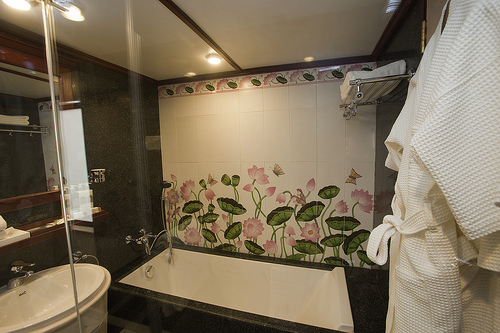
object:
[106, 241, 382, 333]
bathtub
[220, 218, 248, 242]
leaves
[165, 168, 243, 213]
flowers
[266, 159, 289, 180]
butterfly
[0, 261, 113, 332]
sink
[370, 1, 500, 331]
robe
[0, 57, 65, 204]
mirror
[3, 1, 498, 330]
bathroom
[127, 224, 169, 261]
spout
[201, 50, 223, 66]
light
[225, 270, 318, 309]
mable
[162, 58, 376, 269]
tile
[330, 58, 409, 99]
towel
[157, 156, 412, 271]
design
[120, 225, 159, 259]
faucet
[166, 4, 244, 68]
line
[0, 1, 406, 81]
ceiling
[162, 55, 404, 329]
wall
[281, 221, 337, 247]
lily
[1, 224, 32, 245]
dish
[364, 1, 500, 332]
bathrobe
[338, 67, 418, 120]
rack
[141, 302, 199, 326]
tile